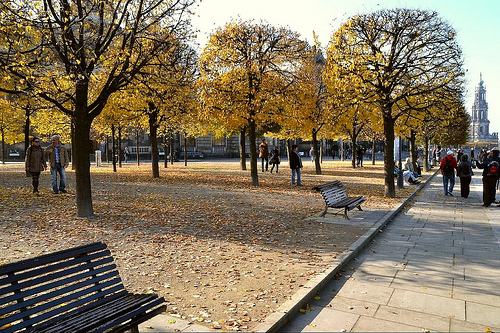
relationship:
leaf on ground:
[1, 158, 438, 333] [1, 158, 438, 333]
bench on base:
[310, 179, 368, 221] [301, 197, 394, 232]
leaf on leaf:
[1, 158, 438, 333] [322, 8, 463, 205]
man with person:
[438, 149, 458, 196] [457, 152, 476, 200]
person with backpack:
[476, 146, 499, 205] [482, 159, 499, 182]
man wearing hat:
[438, 149, 458, 196] [444, 148, 457, 157]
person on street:
[457, 152, 476, 200] [262, 157, 499, 333]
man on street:
[438, 149, 458, 196] [262, 157, 499, 333]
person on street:
[476, 146, 499, 205] [262, 157, 499, 333]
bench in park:
[0, 240, 173, 333] [2, 2, 497, 333]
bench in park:
[310, 179, 368, 221] [2, 2, 497, 333]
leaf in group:
[312, 292, 324, 302] [1, 158, 438, 333]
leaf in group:
[363, 302, 373, 312] [1, 158, 438, 333]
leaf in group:
[376, 227, 384, 234] [1, 158, 438, 333]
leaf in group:
[249, 270, 258, 280] [1, 158, 438, 333]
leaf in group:
[327, 241, 338, 249] [1, 158, 438, 333]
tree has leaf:
[322, 8, 463, 205] [325, 23, 347, 38]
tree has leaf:
[322, 8, 463, 205] [327, 48, 335, 54]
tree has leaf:
[322, 8, 463, 205] [326, 78, 335, 89]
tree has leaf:
[322, 8, 463, 205] [369, 122, 382, 131]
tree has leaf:
[322, 8, 463, 205] [322, 103, 331, 109]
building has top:
[463, 71, 499, 157] [474, 70, 487, 87]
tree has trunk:
[191, 12, 331, 192] [245, 125, 263, 185]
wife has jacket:
[20, 136, 49, 198] [25, 136, 50, 180]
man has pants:
[45, 132, 72, 196] [48, 159, 70, 197]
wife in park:
[20, 136, 49, 198] [2, 2, 497, 333]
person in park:
[45, 132, 72, 196] [2, 2, 497, 333]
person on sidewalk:
[457, 152, 476, 200] [262, 157, 499, 333]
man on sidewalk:
[438, 149, 458, 196] [262, 157, 499, 333]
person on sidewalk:
[476, 146, 499, 205] [262, 157, 499, 333]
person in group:
[457, 152, 476, 200] [436, 147, 499, 207]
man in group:
[438, 149, 458, 196] [436, 147, 499, 207]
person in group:
[476, 146, 499, 205] [436, 147, 499, 207]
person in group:
[392, 157, 420, 187] [389, 153, 426, 186]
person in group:
[405, 154, 415, 181] [436, 147, 499, 207]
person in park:
[476, 146, 499, 205] [2, 2, 497, 333]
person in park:
[457, 152, 476, 200] [2, 2, 497, 333]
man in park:
[438, 149, 458, 196] [2, 2, 497, 333]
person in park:
[392, 157, 420, 187] [2, 2, 497, 333]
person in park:
[405, 154, 415, 181] [2, 2, 497, 333]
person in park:
[286, 141, 308, 188] [2, 2, 497, 333]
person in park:
[255, 137, 271, 172] [2, 2, 497, 333]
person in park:
[268, 143, 283, 175] [2, 2, 497, 333]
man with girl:
[255, 137, 271, 172] [268, 143, 283, 175]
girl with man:
[268, 143, 283, 175] [255, 137, 271, 172]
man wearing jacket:
[476, 146, 499, 205] [473, 153, 500, 184]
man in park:
[476, 146, 499, 205] [2, 2, 497, 333]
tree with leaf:
[322, 8, 463, 205] [326, 78, 335, 89]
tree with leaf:
[191, 12, 331, 192] [209, 37, 220, 45]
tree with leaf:
[3, 2, 190, 221] [17, 57, 26, 70]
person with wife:
[45, 132, 72, 196] [20, 136, 49, 198]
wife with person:
[20, 136, 49, 198] [45, 132, 72, 196]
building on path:
[463, 71, 499, 157] [262, 157, 499, 333]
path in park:
[262, 157, 499, 333] [2, 2, 497, 333]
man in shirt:
[438, 149, 458, 196] [436, 150, 459, 175]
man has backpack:
[441, 149, 458, 181] [443, 157, 455, 177]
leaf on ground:
[376, 227, 384, 234] [1, 158, 438, 333]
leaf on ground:
[327, 241, 338, 249] [1, 158, 438, 333]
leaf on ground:
[363, 302, 373, 312] [1, 158, 438, 333]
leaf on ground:
[312, 292, 324, 302] [1, 158, 438, 333]